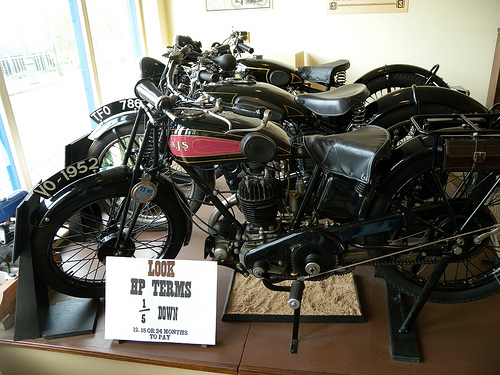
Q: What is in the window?
A: Motorcycles.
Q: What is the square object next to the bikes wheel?
A: Sign.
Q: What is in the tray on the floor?
A: Sawdust.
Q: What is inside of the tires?
A: Metal spokes.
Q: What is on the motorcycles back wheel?
A: Metal rack.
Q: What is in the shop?
A: Bikes.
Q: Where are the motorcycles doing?
A: Being displayed.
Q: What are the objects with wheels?
A: Motorcycles.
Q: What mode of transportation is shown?
A: Motorcycle.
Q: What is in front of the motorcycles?
A: Window.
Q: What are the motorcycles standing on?
A: Stands.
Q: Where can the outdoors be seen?
A: Through the window.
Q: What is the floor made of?
A: Wood.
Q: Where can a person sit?
A: Motorcycle seats.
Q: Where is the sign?
A: In front of the window.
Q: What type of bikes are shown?
A: Motorized.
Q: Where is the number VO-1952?
A: Front tire of the closest bike.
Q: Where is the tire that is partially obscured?
A: Back tire of the closest bike.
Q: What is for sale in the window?
A: Motorcycles.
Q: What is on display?
A: Motorcycles.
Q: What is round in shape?
A: Tires.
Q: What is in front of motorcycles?
A: Window.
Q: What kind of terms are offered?
A: HP.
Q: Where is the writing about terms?
A: On sign.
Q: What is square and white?
A: Sign.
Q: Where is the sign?
A: In front of motorcycle.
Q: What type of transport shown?
A: Motorcycles.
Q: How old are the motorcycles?
A: The motorcycles are from the 1950's so the are multiple years old.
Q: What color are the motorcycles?
A: The motocycles are black.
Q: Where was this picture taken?
A: This picture was taken in a motorcycle shop.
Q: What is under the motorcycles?
A: There is a box of sand under the motorcycles.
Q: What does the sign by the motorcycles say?
A: The sign says look hp terms 1/5 down.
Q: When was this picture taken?
A: It was taken in the day time.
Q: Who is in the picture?
A: Nobody is in the picture.